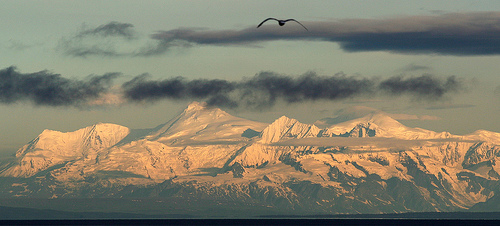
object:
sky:
[4, 101, 57, 130]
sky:
[294, 0, 383, 18]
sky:
[146, 47, 240, 77]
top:
[184, 98, 208, 111]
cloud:
[63, 19, 136, 58]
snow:
[184, 135, 245, 147]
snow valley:
[5, 98, 497, 220]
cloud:
[149, 21, 264, 50]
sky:
[407, 100, 499, 125]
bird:
[256, 17, 310, 31]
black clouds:
[0, 64, 90, 111]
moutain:
[90, 138, 174, 180]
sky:
[0, 0, 93, 44]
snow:
[356, 155, 384, 172]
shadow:
[239, 122, 259, 138]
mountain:
[149, 97, 274, 145]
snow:
[271, 131, 380, 147]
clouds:
[392, 62, 437, 76]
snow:
[382, 122, 433, 142]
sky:
[253, 38, 339, 75]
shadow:
[87, 168, 154, 182]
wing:
[254, 17, 281, 29]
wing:
[281, 17, 310, 31]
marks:
[221, 150, 387, 210]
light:
[7, 121, 170, 185]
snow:
[88, 149, 148, 174]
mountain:
[322, 109, 409, 140]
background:
[337, 0, 500, 60]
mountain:
[91, 138, 181, 187]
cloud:
[391, 110, 440, 122]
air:
[0, 2, 106, 40]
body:
[275, 18, 289, 27]